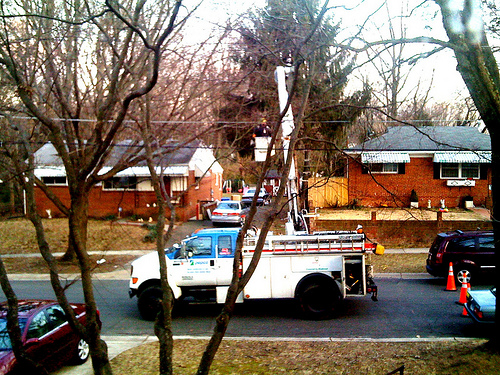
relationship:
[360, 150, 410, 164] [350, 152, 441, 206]
awning on a house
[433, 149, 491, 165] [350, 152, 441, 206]
awning on a house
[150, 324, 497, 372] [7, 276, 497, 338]
curb next to a street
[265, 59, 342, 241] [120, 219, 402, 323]
crane on a truck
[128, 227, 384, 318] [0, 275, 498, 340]
truck on road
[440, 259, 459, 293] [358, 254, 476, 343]
cone blocking a street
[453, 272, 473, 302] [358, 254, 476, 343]
cone blocking a street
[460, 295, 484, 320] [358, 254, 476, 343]
cone blocking a street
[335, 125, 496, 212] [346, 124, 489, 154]
building with a roof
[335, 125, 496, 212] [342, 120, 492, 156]
building with a roof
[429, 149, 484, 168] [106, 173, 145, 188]
awning hanging over a window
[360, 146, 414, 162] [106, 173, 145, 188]
awning hanging over a window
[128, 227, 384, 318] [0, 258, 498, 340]
truck on a road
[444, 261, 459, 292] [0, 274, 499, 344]
cone on a street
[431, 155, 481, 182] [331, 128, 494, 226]
window on a building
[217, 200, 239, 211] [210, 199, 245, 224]
rear window on a vehicle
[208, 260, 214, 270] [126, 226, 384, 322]
door handle on a truck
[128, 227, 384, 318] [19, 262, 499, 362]
truck in road